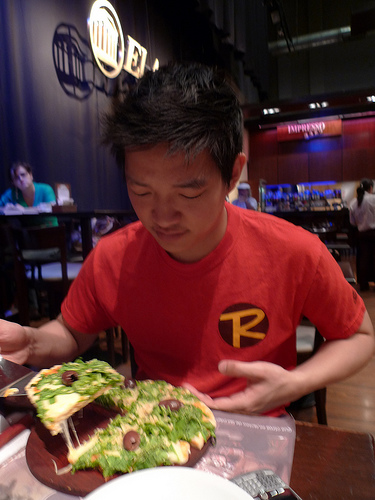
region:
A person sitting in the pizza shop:
[12, 31, 374, 486]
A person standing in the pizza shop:
[347, 176, 374, 242]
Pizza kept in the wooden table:
[48, 375, 211, 468]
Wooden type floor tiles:
[351, 386, 374, 413]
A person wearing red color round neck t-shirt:
[113, 252, 258, 309]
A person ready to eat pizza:
[12, 146, 312, 481]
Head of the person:
[95, 81, 267, 250]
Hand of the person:
[236, 281, 373, 399]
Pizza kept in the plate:
[38, 374, 211, 472]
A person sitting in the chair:
[9, 157, 65, 222]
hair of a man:
[198, 110, 247, 158]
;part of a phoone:
[240, 455, 246, 491]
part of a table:
[308, 436, 331, 470]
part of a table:
[305, 414, 339, 464]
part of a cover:
[243, 419, 260, 439]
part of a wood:
[292, 441, 319, 482]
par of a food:
[148, 426, 173, 448]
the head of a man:
[99, 52, 280, 283]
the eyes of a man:
[97, 152, 259, 232]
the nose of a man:
[141, 206, 196, 240]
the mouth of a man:
[147, 208, 244, 259]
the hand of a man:
[200, 345, 290, 427]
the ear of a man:
[215, 97, 275, 207]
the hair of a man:
[106, 26, 282, 203]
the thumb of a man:
[216, 350, 271, 404]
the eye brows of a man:
[101, 149, 269, 215]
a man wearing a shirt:
[42, 17, 331, 381]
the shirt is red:
[79, 233, 298, 417]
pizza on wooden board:
[39, 359, 196, 495]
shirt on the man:
[88, 208, 352, 371]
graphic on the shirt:
[213, 295, 270, 345]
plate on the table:
[87, 468, 254, 499]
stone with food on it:
[28, 377, 219, 490]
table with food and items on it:
[298, 415, 369, 488]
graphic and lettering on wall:
[83, 2, 169, 79]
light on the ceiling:
[256, 100, 336, 120]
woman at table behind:
[4, 159, 81, 272]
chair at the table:
[18, 206, 124, 294]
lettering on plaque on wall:
[274, 125, 327, 140]